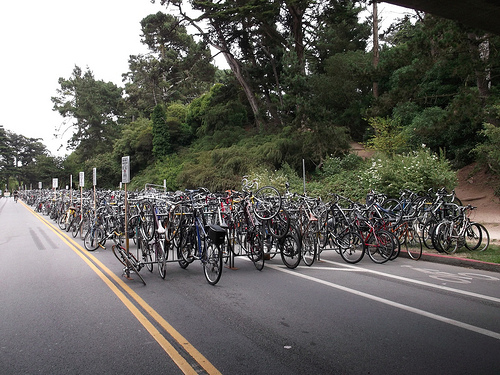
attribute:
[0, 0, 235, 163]
sky — white, grey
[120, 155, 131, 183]
sign — white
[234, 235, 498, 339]
lines — white, painted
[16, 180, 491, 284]
bikes — many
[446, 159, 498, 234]
trail — dirt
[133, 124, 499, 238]
hill — brown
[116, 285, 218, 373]
lines — yellow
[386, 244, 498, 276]
curb — concrete, red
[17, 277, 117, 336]
road — dark, grey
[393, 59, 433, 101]
leaves — green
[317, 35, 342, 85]
leaves — green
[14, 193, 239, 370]
lines — yellow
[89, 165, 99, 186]
sign — white